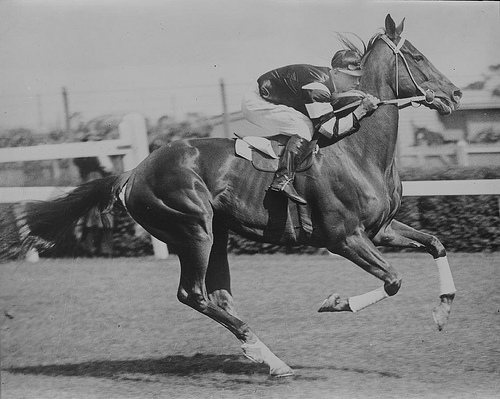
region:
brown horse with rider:
[117, 13, 449, 324]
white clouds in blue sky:
[80, 26, 114, 57]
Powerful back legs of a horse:
[125, 144, 297, 393]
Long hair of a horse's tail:
[0, 168, 122, 256]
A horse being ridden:
[3, 14, 467, 377]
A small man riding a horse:
[241, 49, 380, 204]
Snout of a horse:
[428, 54, 465, 117]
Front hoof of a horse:
[313, 290, 341, 312]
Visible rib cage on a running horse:
[226, 166, 274, 232]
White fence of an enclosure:
[2, 119, 167, 259]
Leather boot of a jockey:
[269, 135, 308, 205]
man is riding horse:
[240, 40, 370, 179]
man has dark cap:
[319, 46, 371, 84]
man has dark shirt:
[280, 60, 315, 101]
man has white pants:
[211, 92, 303, 135]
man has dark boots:
[270, 133, 312, 199]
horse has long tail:
[8, 153, 118, 265]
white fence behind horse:
[22, 106, 498, 251]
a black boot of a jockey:
[268, 137, 309, 204]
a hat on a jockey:
[329, 51, 364, 78]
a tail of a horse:
[3, 168, 135, 266]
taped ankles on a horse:
[344, 284, 389, 316]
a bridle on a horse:
[355, 16, 463, 112]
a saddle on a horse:
[235, 125, 317, 175]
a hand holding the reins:
[353, 90, 379, 122]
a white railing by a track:
[2, 112, 148, 163]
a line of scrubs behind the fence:
[445, 170, 497, 250]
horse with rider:
[107, 28, 497, 290]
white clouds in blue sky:
[157, 3, 197, 40]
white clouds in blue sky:
[95, 11, 142, 39]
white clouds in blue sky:
[2, 13, 57, 38]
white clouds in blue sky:
[167, 25, 231, 56]